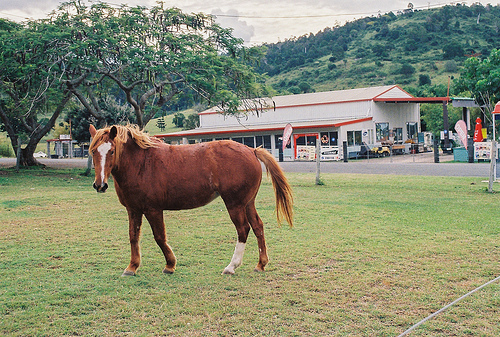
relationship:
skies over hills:
[0, 0, 497, 62] [0, 5, 496, 132]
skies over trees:
[0, 0, 497, 62] [221, 5, 496, 136]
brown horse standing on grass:
[83, 120, 297, 278] [17, 207, 491, 330]